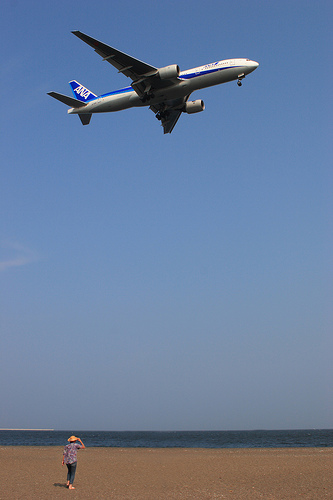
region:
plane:
[35, 18, 257, 138]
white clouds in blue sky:
[234, 221, 266, 245]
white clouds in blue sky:
[208, 288, 265, 324]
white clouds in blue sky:
[106, 262, 149, 318]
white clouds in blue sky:
[129, 319, 175, 387]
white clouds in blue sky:
[36, 216, 85, 276]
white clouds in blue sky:
[75, 248, 144, 301]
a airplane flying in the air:
[47, 28, 261, 136]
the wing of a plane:
[71, 27, 179, 91]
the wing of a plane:
[146, 93, 187, 135]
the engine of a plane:
[133, 63, 189, 91]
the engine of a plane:
[179, 94, 208, 117]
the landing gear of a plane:
[234, 72, 248, 88]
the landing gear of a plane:
[139, 83, 154, 102]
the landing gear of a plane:
[151, 104, 172, 123]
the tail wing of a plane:
[44, 89, 85, 110]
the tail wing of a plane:
[79, 109, 92, 127]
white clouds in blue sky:
[98, 189, 131, 212]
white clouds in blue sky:
[193, 254, 230, 298]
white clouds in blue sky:
[105, 292, 145, 328]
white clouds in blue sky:
[192, 318, 221, 354]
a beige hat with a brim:
[64, 434, 78, 442]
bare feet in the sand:
[63, 479, 76, 489]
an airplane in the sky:
[44, 25, 265, 148]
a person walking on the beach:
[57, 433, 91, 489]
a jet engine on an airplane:
[127, 63, 186, 86]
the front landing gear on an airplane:
[234, 73, 245, 88]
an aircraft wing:
[68, 27, 188, 100]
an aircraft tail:
[42, 78, 100, 130]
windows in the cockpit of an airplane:
[242, 54, 252, 63]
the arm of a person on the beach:
[74, 435, 87, 452]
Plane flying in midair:
[25, 22, 277, 143]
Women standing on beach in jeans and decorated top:
[9, 405, 235, 494]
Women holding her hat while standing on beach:
[14, 407, 236, 494]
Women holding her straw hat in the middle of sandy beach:
[14, 404, 227, 494]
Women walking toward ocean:
[14, 409, 238, 495]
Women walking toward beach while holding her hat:
[17, 413, 220, 494]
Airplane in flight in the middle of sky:
[27, 16, 274, 137]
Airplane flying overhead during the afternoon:
[35, 16, 267, 159]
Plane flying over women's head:
[32, 22, 325, 495]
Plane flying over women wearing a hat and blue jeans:
[39, 23, 326, 491]